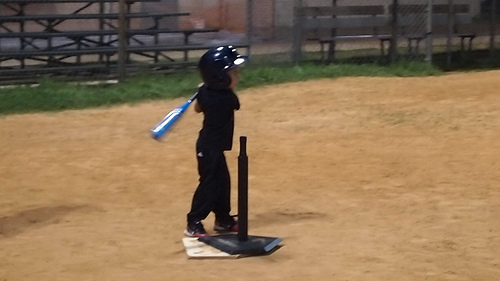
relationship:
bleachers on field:
[21, 15, 198, 92] [45, 20, 477, 247]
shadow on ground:
[12, 190, 107, 247] [70, 121, 141, 279]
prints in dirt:
[363, 189, 455, 229] [319, 66, 481, 239]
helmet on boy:
[185, 43, 249, 90] [154, 37, 254, 196]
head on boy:
[195, 61, 270, 95] [154, 37, 254, 196]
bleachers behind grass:
[21, 15, 198, 92] [114, 75, 171, 96]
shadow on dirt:
[12, 190, 107, 247] [319, 66, 481, 239]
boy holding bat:
[185, 42, 247, 235] [125, 82, 183, 125]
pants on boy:
[186, 152, 279, 269] [154, 37, 254, 196]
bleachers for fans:
[0, 0, 254, 83] [250, 6, 401, 55]